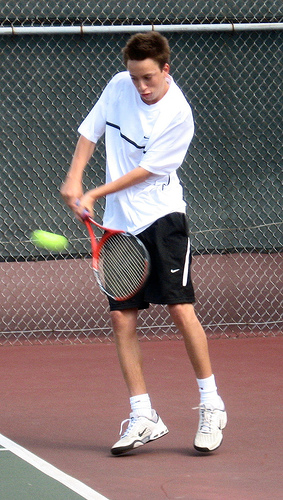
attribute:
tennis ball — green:
[28, 226, 70, 255]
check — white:
[166, 264, 182, 276]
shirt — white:
[76, 68, 196, 238]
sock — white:
[195, 373, 219, 403]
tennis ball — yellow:
[26, 230, 71, 255]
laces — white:
[114, 411, 142, 440]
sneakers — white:
[110, 411, 170, 457]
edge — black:
[111, 436, 147, 454]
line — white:
[180, 232, 194, 290]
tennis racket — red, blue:
[71, 205, 149, 304]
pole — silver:
[0, 20, 281, 41]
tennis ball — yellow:
[28, 228, 68, 259]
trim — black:
[112, 422, 227, 456]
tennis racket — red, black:
[62, 193, 170, 331]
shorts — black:
[87, 215, 199, 317]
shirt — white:
[92, 74, 182, 238]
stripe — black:
[110, 104, 148, 160]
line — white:
[16, 444, 76, 492]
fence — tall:
[177, 40, 273, 258]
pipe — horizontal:
[163, 11, 278, 41]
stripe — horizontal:
[85, 111, 155, 156]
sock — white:
[128, 392, 155, 419]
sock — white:
[195, 373, 224, 407]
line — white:
[27, 453, 75, 488]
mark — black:
[133, 426, 148, 437]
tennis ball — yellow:
[30, 220, 66, 258]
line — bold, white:
[0, 434, 106, 498]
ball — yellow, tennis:
[18, 208, 73, 259]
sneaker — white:
[95, 400, 182, 470]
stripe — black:
[104, 110, 175, 170]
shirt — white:
[75, 63, 224, 238]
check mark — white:
[169, 267, 178, 272]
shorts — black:
[102, 211, 196, 311]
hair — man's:
[124, 30, 172, 71]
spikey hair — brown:
[123, 28, 169, 66]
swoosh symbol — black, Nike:
[137, 427, 147, 436]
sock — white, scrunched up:
[128, 394, 151, 410]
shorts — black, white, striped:
[118, 224, 211, 290]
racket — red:
[62, 205, 163, 306]